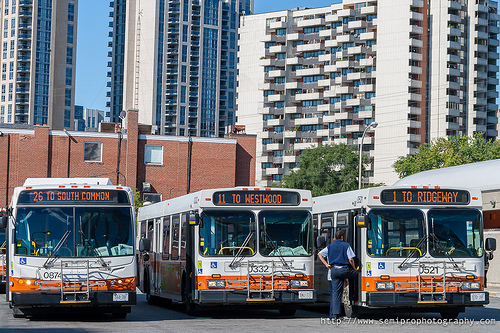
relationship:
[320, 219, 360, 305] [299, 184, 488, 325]
man stands on bus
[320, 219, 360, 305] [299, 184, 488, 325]
man next to bus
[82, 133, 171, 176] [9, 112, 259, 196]
windows on building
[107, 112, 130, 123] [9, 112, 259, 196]
satellite dish on building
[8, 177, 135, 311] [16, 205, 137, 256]
bus has window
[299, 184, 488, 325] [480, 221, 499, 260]
bus has side mirror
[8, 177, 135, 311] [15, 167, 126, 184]
bus has top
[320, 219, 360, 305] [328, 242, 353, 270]
man has sweater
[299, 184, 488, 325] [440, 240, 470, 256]
bus has wheel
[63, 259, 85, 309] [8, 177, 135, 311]
bike rack on bus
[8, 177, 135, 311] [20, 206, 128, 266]
bus has windshield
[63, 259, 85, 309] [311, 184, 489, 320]
bike rack on bus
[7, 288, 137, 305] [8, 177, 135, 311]
bumper on bus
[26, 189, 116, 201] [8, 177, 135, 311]
digital board of bus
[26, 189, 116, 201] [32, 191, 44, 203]
digital board with number 26